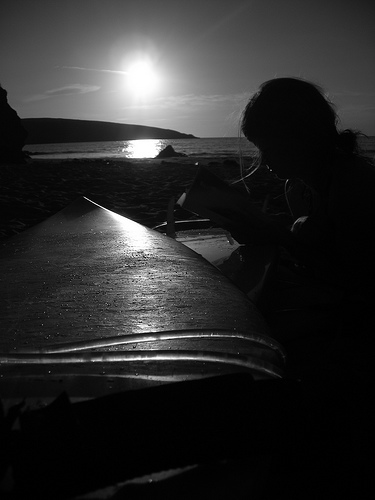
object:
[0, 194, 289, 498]
surfboard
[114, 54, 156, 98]
sun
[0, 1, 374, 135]
sky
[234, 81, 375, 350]
woman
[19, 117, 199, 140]
mountain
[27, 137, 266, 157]
water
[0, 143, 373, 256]
sand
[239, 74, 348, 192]
hair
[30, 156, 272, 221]
sand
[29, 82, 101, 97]
clouds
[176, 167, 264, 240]
book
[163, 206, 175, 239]
fin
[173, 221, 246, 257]
surfboard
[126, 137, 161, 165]
reflection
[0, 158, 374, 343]
beach